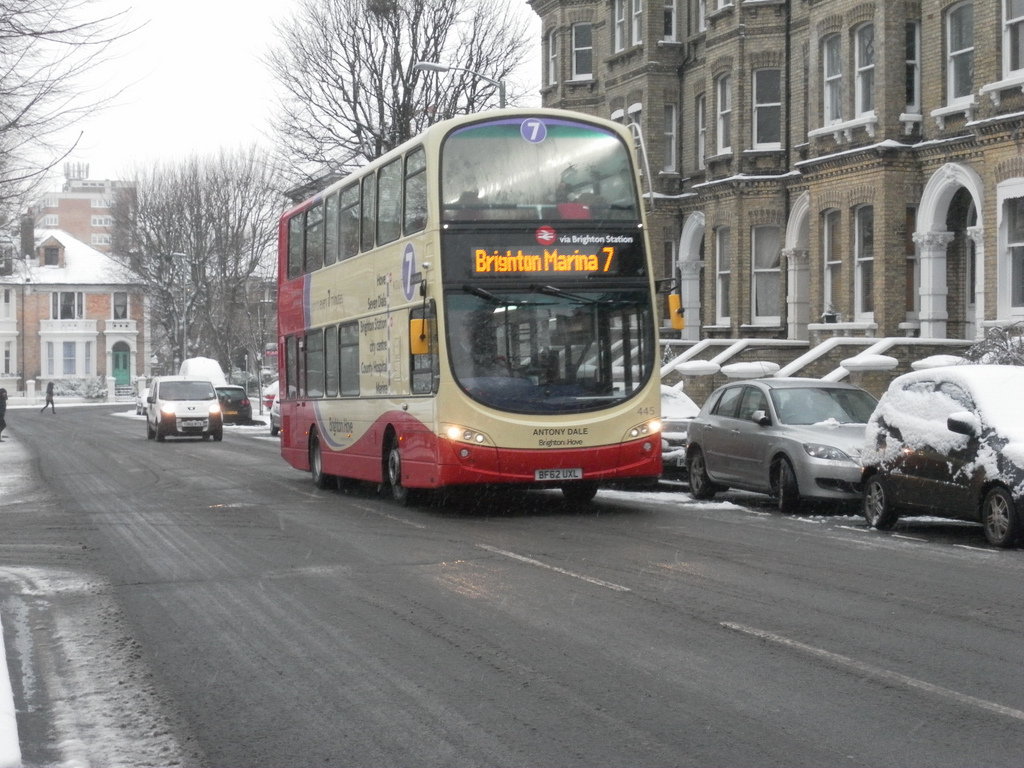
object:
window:
[694, 88, 707, 171]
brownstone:
[789, 0, 909, 388]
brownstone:
[684, 0, 790, 409]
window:
[715, 66, 733, 156]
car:
[681, 375, 884, 514]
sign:
[469, 245, 619, 277]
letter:
[476, 249, 489, 271]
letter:
[485, 256, 494, 273]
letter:
[498, 254, 507, 272]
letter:
[544, 248, 560, 272]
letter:
[588, 254, 601, 271]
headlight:
[161, 403, 177, 414]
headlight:
[208, 404, 221, 413]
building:
[0, 213, 158, 401]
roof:
[2, 228, 155, 285]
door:
[112, 350, 131, 385]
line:
[471, 542, 632, 594]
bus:
[277, 105, 663, 507]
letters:
[517, 250, 526, 272]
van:
[145, 375, 224, 442]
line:
[350, 502, 430, 529]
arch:
[911, 158, 987, 342]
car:
[208, 385, 254, 426]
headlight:
[444, 425, 461, 442]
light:
[647, 419, 663, 431]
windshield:
[438, 115, 641, 226]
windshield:
[443, 287, 659, 415]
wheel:
[309, 424, 366, 490]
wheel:
[388, 431, 446, 508]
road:
[2, 402, 1018, 768]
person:
[39, 380, 56, 413]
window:
[321, 188, 340, 269]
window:
[358, 166, 379, 254]